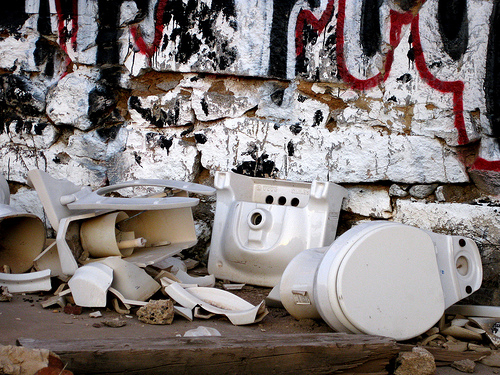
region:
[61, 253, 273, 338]
Broken toilet pieces on the ground.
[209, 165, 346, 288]
white sink against the wall.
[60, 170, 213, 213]
white toilet seat in the forefront.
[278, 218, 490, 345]
White toilet on the ground.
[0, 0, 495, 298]
Rock wall in the background.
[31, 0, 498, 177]
Graffiti on the wall.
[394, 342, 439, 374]
Rock on the ground.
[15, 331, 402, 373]
Wood beam in the forefront.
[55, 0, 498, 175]
Red coloring on the wall.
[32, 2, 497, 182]
Black coloring on the wall.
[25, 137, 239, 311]
Broken toilet laying on the ground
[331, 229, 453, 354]
Toilet lid on the toilet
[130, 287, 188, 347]
Rock beside the toilet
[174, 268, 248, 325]
Piece of toilet seat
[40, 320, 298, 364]
Wooden log beside the pile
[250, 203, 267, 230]
Sink drain hole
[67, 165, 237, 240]
Toilet seat on top of pile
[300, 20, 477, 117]
Grafitti on the wall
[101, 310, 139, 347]
Piece of rock on the ground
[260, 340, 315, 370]
Wood has crack in it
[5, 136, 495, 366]
a pile of discarded material is near a wall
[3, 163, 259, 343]
broken porcelain is white in the pile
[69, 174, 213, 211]
a plastic toilet seat is on top of the pile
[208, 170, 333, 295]
the bottom of a white sink is on its side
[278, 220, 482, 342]
a white toilet has been discarded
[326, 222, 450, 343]
the seat of the toilet is closed while on the side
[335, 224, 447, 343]
the lid is closed on the toilet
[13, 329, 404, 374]
a piece of wood has been thrown out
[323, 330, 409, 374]
the wood is rotted on the end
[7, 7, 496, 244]
the stone wall is painted white and has grafitti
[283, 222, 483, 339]
White toilet on its side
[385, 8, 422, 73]
Red spray paint on building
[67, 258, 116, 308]
Broken piece of ceramic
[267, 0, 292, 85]
Black paint sprayed on building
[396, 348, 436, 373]
Large brown rock by toilet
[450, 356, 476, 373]
Small brown rock by toilet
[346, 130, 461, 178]
White spray paint on wall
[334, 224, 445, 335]
White lid on toilet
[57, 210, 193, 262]
Broken back to toilet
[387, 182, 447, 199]
Small rocks on wall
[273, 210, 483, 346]
toilet on the ground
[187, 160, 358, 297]
sink on the ground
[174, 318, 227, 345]
broken peice of porcelain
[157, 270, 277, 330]
broken peice of porcelain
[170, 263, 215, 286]
broken peice of porcelain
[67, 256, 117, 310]
broken peice of porcelain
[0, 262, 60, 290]
broken peice of porcelain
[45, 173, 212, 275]
broken peice of porcelain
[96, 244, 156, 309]
broken peice of porcelain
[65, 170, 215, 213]
broken peice of porcelain